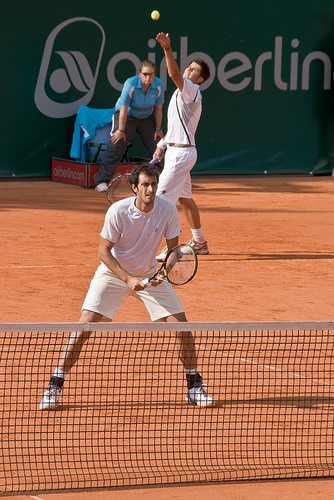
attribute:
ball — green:
[149, 9, 162, 22]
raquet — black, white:
[140, 245, 197, 298]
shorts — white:
[80, 262, 186, 324]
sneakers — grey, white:
[40, 382, 217, 412]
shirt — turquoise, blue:
[113, 76, 166, 121]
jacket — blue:
[70, 106, 120, 162]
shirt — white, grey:
[163, 77, 203, 145]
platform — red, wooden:
[50, 156, 155, 190]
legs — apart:
[40, 267, 215, 409]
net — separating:
[0, 321, 334, 497]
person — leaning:
[93, 60, 166, 192]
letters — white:
[108, 35, 333, 92]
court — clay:
[0, 173, 331, 499]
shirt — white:
[100, 197, 179, 275]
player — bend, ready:
[39, 164, 216, 408]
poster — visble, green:
[0, 1, 334, 177]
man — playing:
[153, 32, 210, 261]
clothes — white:
[82, 196, 187, 323]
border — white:
[0, 320, 334, 333]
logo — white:
[32, 16, 105, 121]